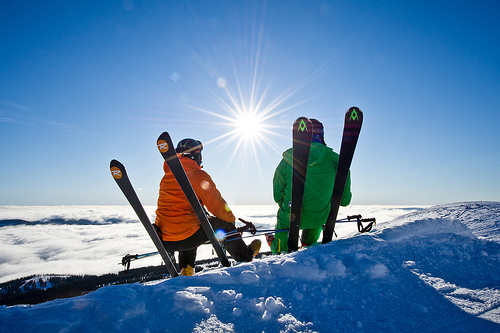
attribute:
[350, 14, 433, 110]
sky — clear